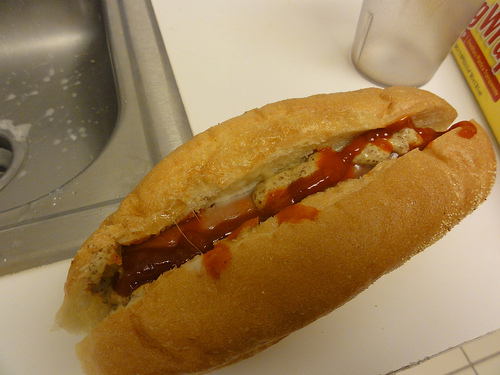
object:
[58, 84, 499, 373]
hot dog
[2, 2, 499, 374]
counter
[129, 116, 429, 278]
sauce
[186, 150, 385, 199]
mustard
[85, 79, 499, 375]
bun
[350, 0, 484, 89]
cup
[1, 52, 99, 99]
bubbles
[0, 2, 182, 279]
sink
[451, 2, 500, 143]
box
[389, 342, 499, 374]
tile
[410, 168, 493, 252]
seeds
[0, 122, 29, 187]
drain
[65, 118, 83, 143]
bubbles